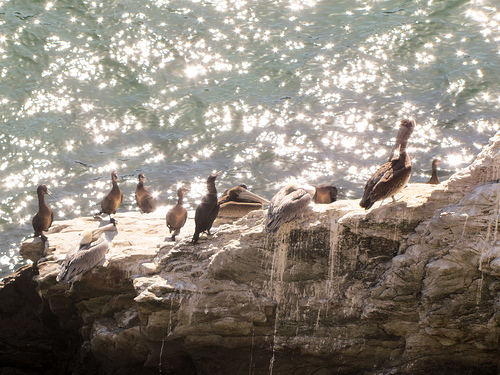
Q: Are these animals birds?
A: Yes, all the animals are birds.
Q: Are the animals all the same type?
A: Yes, all the animals are birds.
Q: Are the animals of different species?
A: No, all the animals are birds.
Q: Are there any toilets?
A: No, there are no toilets.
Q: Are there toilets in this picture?
A: No, there are no toilets.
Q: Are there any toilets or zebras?
A: No, there are no toilets or zebras.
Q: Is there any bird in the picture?
A: Yes, there is a bird.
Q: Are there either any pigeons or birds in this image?
A: Yes, there is a bird.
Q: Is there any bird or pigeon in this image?
A: Yes, there is a bird.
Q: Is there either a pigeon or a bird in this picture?
A: Yes, there is a bird.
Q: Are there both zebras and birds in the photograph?
A: No, there is a bird but no zebras.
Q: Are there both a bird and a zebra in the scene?
A: No, there is a bird but no zebras.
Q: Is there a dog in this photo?
A: No, there are no dogs.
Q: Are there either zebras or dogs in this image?
A: No, there are no dogs or zebras.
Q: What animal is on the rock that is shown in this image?
A: The animal is a bird.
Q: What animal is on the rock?
A: The animal is a bird.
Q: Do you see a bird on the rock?
A: Yes, there is a bird on the rock.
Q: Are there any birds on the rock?
A: Yes, there is a bird on the rock.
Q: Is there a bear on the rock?
A: No, there is a bird on the rock.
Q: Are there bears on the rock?
A: No, there is a bird on the rock.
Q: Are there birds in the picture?
A: Yes, there is a bird.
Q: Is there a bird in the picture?
A: Yes, there is a bird.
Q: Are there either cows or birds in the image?
A: Yes, there is a bird.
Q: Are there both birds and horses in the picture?
A: No, there is a bird but no horses.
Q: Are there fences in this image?
A: No, there are no fences.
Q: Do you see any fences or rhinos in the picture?
A: No, there are no fences or rhinos.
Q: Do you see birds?
A: Yes, there is a bird.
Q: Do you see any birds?
A: Yes, there is a bird.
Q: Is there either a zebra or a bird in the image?
A: Yes, there is a bird.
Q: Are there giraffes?
A: No, there are no giraffes.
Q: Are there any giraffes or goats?
A: No, there are no giraffes or goats.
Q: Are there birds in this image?
A: Yes, there is a bird.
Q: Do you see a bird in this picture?
A: Yes, there is a bird.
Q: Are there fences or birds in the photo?
A: Yes, there is a bird.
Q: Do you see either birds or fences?
A: Yes, there is a bird.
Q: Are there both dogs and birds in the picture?
A: No, there is a bird but no dogs.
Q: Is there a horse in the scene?
A: No, there are no horses.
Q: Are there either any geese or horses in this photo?
A: No, there are no horses or geese.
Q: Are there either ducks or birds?
A: Yes, there is a bird.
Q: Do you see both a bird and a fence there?
A: No, there is a bird but no fences.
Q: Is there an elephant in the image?
A: No, there are no elephants.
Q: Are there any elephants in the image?
A: No, there are no elephants.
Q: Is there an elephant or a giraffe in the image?
A: No, there are no elephants or giraffes.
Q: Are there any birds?
A: Yes, there is a bird.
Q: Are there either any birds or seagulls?
A: Yes, there is a bird.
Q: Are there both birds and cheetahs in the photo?
A: No, there is a bird but no cheetahs.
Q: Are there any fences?
A: No, there are no fences.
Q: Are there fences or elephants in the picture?
A: No, there are no fences or elephants.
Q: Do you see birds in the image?
A: Yes, there is a bird.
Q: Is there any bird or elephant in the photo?
A: Yes, there is a bird.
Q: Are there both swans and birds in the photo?
A: No, there is a bird but no swans.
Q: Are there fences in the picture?
A: No, there are no fences.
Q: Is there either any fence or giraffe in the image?
A: No, there are no fences or giraffes.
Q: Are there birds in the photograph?
A: Yes, there is a bird.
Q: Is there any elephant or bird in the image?
A: Yes, there is a bird.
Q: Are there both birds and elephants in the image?
A: No, there is a bird but no elephants.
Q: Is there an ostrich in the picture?
A: No, there are no ostriches.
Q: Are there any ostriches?
A: No, there are no ostriches.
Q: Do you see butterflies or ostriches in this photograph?
A: No, there are no ostriches or butterflies.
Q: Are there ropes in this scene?
A: No, there are no ropes.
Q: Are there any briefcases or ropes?
A: No, there are no ropes or briefcases.